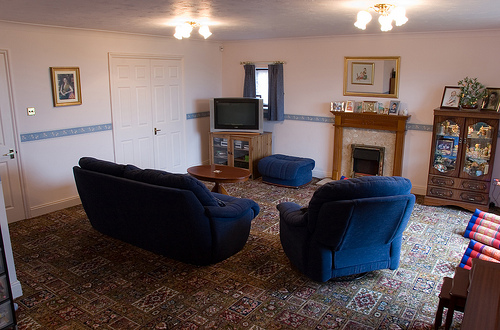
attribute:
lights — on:
[159, 4, 224, 50]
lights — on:
[325, 0, 428, 43]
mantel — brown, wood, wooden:
[327, 115, 414, 131]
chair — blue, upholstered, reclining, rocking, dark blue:
[276, 161, 423, 287]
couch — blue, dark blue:
[68, 153, 259, 265]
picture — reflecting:
[347, 61, 375, 83]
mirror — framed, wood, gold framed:
[339, 51, 402, 100]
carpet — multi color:
[15, 159, 474, 327]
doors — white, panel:
[111, 55, 185, 170]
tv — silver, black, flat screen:
[205, 95, 266, 133]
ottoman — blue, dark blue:
[255, 148, 316, 189]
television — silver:
[208, 97, 259, 128]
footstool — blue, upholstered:
[255, 148, 314, 192]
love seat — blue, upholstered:
[71, 156, 262, 273]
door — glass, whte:
[429, 121, 492, 174]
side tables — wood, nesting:
[428, 271, 469, 327]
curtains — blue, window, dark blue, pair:
[240, 56, 289, 122]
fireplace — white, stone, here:
[332, 106, 409, 173]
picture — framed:
[50, 66, 85, 107]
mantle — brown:
[327, 101, 406, 127]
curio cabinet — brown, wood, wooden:
[410, 81, 500, 213]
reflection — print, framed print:
[350, 60, 374, 84]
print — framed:
[350, 58, 378, 84]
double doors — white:
[116, 55, 200, 173]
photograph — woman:
[56, 73, 73, 99]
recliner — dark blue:
[271, 168, 418, 292]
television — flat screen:
[201, 93, 268, 134]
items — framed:
[326, 93, 409, 116]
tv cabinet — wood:
[207, 131, 276, 175]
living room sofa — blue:
[69, 155, 264, 264]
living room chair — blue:
[274, 174, 421, 285]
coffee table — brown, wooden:
[188, 157, 249, 191]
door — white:
[149, 61, 189, 165]